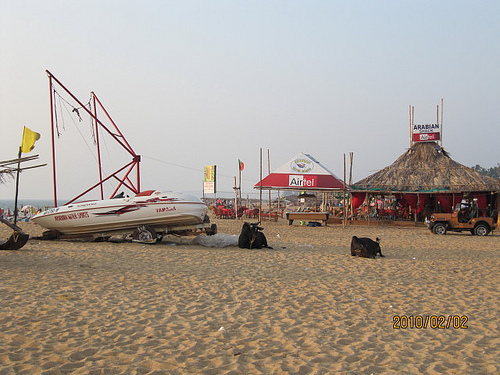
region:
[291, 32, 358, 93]
part of the sky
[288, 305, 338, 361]
part of some sand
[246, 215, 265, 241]
head of a cow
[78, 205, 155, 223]
side of a boat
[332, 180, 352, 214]
part of some stands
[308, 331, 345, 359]
part of some footpaths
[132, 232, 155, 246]
part of a wheel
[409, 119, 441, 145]
part of a banner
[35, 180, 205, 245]
this is a motor boat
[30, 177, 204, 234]
the motor boat is parked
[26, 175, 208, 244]
the motor boat is white in color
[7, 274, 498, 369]
sand is all over the place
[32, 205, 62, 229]
the front is sharp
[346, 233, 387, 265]
this is a bag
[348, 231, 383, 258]
the bag is black in color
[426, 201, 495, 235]
this is a truck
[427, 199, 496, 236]
the truck is brown in color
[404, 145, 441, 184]
the roof is thatched with grass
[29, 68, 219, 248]
BOAT IS RED AND WHITE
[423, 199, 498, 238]
A JEEP PARKED ON BEACH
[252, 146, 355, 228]
A TENT WITH AIRTEL ON IT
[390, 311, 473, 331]
THE DATE OF PHOTO 2010/02/02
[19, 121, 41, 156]
A FLAG IS YELLOW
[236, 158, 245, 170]
A FLAG IS RED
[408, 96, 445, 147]
FOUR POLES FOR SIGN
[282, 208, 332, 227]
ONE BENCH ON BEACH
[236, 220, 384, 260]
TWO MOTORS LAYING IN THE SAND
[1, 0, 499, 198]
THE SKY IS CLOUDY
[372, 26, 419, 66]
part of the sky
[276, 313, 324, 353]
part of some sand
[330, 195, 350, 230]
part of a stand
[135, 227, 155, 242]
part of a wheel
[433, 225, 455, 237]
part of a wheel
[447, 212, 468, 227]
side of a car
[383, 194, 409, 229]
front of a hut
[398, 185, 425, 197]
edge of a roof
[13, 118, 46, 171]
yellow flag on a pole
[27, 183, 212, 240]
boat on a trailer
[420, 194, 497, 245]
vehicle on a beach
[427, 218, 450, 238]
front wheel on a vehicle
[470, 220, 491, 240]
rear wheel on a vehicle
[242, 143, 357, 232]
tent on a beach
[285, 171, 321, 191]
sign on a tent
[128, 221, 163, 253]
wheel on a trailer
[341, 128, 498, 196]
roof on a building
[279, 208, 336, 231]
bench on a beach